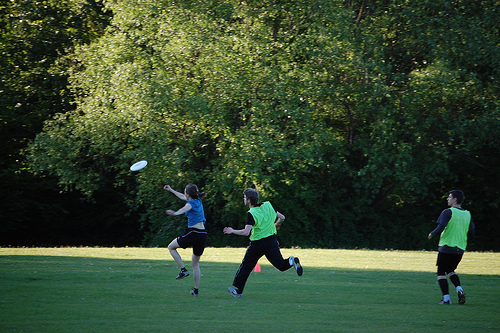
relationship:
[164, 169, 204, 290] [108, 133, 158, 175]
man chasing frisbee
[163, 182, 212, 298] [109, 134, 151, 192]
man chasing frisbee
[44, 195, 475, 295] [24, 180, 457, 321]
sun on grass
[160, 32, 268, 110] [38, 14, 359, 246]
leaves on trees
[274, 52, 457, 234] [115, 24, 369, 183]
leaves on trees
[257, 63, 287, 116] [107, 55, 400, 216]
leaves on trees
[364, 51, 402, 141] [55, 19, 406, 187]
leaves on trees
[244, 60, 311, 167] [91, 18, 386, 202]
leaves on trees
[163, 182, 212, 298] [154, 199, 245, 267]
man wearing shorts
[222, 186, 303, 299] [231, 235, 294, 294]
man wearing black pants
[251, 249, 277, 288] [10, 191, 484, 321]
cone on ground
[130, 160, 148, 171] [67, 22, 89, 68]
frisbee flying in air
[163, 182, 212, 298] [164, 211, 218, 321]
man wearing shorts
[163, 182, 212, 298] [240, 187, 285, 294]
man chasing another man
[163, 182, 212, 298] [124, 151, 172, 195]
man trying to catch a frisbee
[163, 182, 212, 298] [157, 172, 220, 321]
man wearing blue shirt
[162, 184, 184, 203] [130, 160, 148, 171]
arm reaching for frisbee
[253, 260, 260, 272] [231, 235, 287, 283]
cone near black pants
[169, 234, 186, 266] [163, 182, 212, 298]
raised leg of man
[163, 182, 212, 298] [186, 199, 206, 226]
man in blue shirt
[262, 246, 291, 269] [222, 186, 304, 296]
bent leg of man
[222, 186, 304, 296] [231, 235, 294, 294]
man in black pants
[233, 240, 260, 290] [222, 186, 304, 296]
straight leg of man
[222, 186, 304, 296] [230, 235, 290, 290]
man in long pants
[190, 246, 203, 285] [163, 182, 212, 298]
straight leg of man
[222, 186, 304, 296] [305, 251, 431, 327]
man running on green lawn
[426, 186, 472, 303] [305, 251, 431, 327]
man standing on green lawn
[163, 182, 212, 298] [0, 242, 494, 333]
man jumping on grass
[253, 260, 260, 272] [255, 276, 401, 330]
cone in grass